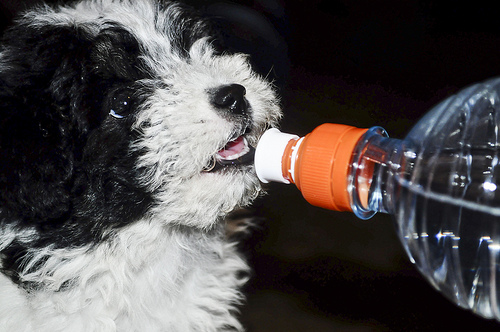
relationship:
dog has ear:
[3, 3, 293, 330] [2, 43, 92, 227]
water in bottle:
[411, 137, 476, 243] [249, 75, 498, 325]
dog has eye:
[3, 3, 293, 330] [94, 73, 148, 123]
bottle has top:
[249, 75, 498, 325] [251, 116, 373, 212]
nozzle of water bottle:
[253, 122, 299, 188] [253, 77, 483, 320]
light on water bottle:
[396, 145, 433, 163] [253, 77, 483, 320]